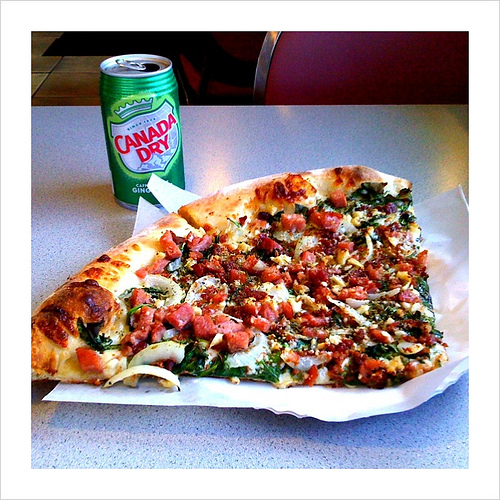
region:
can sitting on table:
[87, 51, 192, 207]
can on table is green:
[90, 44, 197, 209]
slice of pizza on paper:
[33, 158, 453, 408]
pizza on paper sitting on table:
[33, 159, 470, 439]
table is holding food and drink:
[33, 93, 467, 465]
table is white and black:
[31, 99, 468, 466]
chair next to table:
[243, 28, 468, 107]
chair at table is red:
[248, 30, 470, 104]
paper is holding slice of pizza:
[38, 166, 468, 423]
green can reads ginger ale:
[89, 48, 193, 215]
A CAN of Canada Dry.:
[96, 54, 194, 207]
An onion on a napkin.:
[102, 358, 182, 393]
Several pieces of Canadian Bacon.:
[153, 307, 221, 340]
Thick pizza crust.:
[33, 206, 181, 383]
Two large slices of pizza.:
[31, 169, 450, 392]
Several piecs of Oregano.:
[179, 340, 251, 380]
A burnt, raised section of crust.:
[51, 270, 111, 337]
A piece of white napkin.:
[261, 393, 404, 424]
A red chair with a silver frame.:
[236, 33, 465, 100]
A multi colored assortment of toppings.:
[277, 223, 412, 301]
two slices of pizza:
[123, 194, 303, 311]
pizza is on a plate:
[228, 385, 329, 448]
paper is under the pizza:
[346, 400, 454, 425]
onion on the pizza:
[122, 364, 152, 387]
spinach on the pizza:
[182, 353, 212, 374]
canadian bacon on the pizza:
[176, 305, 203, 346]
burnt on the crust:
[56, 286, 105, 336]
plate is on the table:
[257, 397, 335, 449]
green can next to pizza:
[103, 61, 221, 199]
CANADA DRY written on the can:
[105, 128, 180, 164]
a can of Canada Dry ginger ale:
[93, 43, 194, 205]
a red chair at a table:
[249, 31, 468, 102]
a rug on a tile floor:
[41, 31, 170, 56]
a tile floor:
[32, 33, 113, 106]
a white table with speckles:
[30, 105, 468, 468]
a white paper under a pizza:
[41, 179, 466, 419]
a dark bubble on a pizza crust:
[45, 279, 110, 335]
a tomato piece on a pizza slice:
[193, 313, 215, 333]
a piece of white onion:
[105, 362, 186, 391]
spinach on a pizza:
[357, 185, 389, 206]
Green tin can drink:
[72, 52, 207, 209]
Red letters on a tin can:
[102, 118, 189, 164]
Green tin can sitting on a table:
[48, 45, 203, 200]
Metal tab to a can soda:
[107, 50, 157, 77]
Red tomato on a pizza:
[68, 335, 114, 380]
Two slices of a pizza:
[47, 175, 447, 421]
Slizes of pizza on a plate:
[45, 154, 447, 434]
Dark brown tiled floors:
[42, 54, 94, 99]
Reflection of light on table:
[222, 111, 471, 176]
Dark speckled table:
[58, 418, 406, 475]